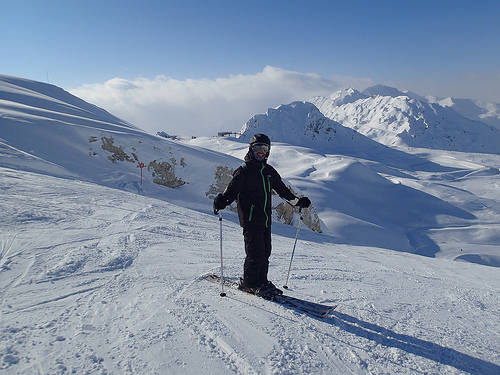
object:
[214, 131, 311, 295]
man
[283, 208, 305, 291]
ski pole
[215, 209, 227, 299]
ski pole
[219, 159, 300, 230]
jacket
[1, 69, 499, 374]
area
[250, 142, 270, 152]
goggles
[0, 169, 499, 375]
snow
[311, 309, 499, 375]
shadow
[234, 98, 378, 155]
hill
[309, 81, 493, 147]
hill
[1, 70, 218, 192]
hill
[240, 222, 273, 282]
pants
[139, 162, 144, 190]
pole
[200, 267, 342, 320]
tracks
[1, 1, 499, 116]
sky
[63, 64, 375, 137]
cloud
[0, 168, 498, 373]
ground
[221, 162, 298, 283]
suit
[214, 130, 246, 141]
structure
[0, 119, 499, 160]
background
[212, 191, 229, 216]
hand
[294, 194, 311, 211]
hand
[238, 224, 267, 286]
leg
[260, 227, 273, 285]
leg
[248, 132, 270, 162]
head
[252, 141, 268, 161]
face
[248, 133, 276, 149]
protective gear